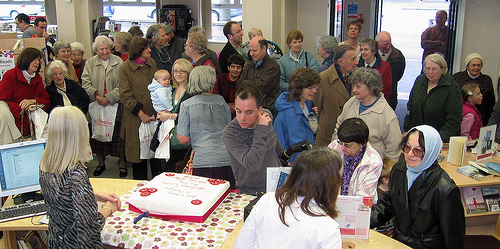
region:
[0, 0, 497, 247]
the large group of people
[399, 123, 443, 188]
the blue scarf on the woman's head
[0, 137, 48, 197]
the computer monitor on the table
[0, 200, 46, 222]
the keyboard on the table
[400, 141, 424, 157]
the glasses on the woman's face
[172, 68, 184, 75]
the glasses on the woman's face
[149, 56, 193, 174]
the woman carrying the baby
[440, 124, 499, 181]
the books on top of the shelf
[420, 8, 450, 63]
the man standing with crossed arms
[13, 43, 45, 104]
a woman wearing a red coat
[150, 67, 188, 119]
a woman holding a baby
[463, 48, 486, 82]
a woman wearing a hat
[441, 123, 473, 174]
a book on the table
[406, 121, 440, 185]
a woman wearing a scarf on her head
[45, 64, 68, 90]
a woman wearing glasses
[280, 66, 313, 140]
a woman wearing a blue jacket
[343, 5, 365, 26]
a sign on the wall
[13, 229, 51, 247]
books under the counter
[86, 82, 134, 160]
a woman holding a bag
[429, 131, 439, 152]
woman wearing white scarf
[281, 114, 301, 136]
woman wearing blue jacket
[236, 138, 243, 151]
man wearing grey sweater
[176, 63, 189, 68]
woman with blonde hair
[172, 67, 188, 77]
woman wearing black glasses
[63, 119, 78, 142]
woman with white hair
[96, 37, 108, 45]
man with grey hair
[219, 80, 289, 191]
Man scratching his ear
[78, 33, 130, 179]
Woman holding a shopping bag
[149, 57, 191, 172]
Woman holding a baby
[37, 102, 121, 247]
Woman in a zebra patterned top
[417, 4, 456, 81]
Man leaning against wall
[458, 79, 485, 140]
Child in a pink vest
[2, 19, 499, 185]
Group of people standing in a store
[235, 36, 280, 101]
Man crossing his arms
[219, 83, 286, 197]
Man in a grey shirt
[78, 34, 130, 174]
Woman in a tan jacket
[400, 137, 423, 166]
a woman wearing glasses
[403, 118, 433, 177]
a woman wearing a scarf on her head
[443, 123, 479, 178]
a book standing on a table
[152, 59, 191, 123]
a woman holding a baby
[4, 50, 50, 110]
a woman wearing a red coat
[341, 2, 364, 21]
a paper hanging on the wall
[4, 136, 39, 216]
a computer on the counter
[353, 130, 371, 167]
a woman wearing earrings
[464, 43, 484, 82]
a woman wearing a hat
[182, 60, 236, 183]
A person is standing up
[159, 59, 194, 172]
A person is standing up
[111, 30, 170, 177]
A person is standing up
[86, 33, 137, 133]
A person is standing up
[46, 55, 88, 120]
A person is standing up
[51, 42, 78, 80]
A person is standing up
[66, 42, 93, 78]
A person is standing up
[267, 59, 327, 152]
A person is standing up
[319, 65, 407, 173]
A person is standing up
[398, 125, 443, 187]
a blue scarf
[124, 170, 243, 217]
a large red and white cake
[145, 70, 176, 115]
a small baby boy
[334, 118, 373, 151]
a woman's short cut hair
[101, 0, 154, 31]
a window of a building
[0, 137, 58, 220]
a large desktop computer